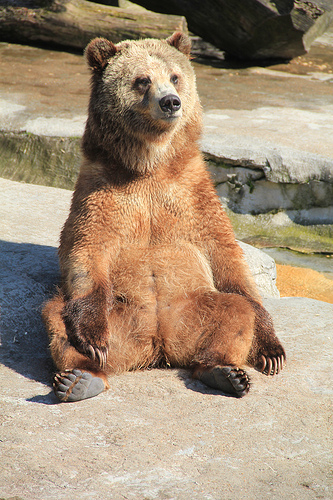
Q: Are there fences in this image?
A: No, there are no fences.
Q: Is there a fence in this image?
A: No, there are no fences.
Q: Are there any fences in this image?
A: No, there are no fences.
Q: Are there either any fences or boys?
A: No, there are no fences or boys.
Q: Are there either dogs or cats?
A: No, there are no dogs or cats.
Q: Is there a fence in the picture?
A: No, there are no fences.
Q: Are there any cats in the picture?
A: No, there are no cats.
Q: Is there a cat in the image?
A: No, there are no cats.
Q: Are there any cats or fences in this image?
A: No, there are no cats or fences.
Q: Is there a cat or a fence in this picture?
A: No, there are no cats or fences.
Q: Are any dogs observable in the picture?
A: No, there are no dogs.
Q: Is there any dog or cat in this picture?
A: No, there are no dogs or cats.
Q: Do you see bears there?
A: Yes, there is a bear.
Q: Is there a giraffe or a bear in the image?
A: Yes, there is a bear.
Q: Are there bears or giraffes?
A: Yes, there is a bear.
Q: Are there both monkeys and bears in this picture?
A: No, there is a bear but no monkeys.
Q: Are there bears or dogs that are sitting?
A: Yes, the bear is sitting.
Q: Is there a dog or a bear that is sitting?
A: Yes, the bear is sitting.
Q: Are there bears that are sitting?
A: Yes, there is a bear that is sitting.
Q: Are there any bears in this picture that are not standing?
A: Yes, there is a bear that is sitting.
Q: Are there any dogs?
A: No, there are no dogs.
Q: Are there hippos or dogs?
A: No, there are no dogs or hippos.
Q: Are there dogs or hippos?
A: No, there are no dogs or hippos.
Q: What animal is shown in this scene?
A: The animal is a bear.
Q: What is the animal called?
A: The animal is a bear.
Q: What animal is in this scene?
A: The animal is a bear.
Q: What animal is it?
A: The animal is a bear.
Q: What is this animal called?
A: This is a bear.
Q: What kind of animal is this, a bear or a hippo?
A: This is a bear.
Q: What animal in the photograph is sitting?
A: The animal is a bear.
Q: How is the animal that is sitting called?
A: The animal is a bear.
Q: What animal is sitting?
A: The animal is a bear.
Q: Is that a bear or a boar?
A: That is a bear.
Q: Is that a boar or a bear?
A: That is a bear.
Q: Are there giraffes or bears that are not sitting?
A: No, there is a bear but it is sitting.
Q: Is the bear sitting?
A: Yes, the bear is sitting.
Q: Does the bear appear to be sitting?
A: Yes, the bear is sitting.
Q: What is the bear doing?
A: The bear is sitting.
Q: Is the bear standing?
A: No, the bear is sitting.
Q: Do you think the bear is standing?
A: No, the bear is sitting.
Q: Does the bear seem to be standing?
A: No, the bear is sitting.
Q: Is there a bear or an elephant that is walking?
A: No, there is a bear but it is sitting.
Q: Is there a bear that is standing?
A: No, there is a bear but it is sitting.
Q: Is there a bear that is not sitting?
A: No, there is a bear but it is sitting.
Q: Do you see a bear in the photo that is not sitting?
A: No, there is a bear but it is sitting.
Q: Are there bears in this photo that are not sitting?
A: No, there is a bear but it is sitting.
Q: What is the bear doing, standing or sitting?
A: The bear is sitting.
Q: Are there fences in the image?
A: No, there are no fences.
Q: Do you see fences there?
A: No, there are no fences.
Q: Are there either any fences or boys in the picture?
A: No, there are no fences or boys.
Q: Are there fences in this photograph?
A: No, there are no fences.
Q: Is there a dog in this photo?
A: No, there are no dogs.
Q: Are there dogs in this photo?
A: No, there are no dogs.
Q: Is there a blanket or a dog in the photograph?
A: No, there are no dogs or blankets.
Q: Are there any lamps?
A: No, there are no lamps.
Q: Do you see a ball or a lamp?
A: No, there are no lamps or balls.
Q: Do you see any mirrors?
A: No, there are no mirrors.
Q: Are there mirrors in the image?
A: No, there are no mirrors.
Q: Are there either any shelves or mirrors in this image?
A: No, there are no mirrors or shelves.